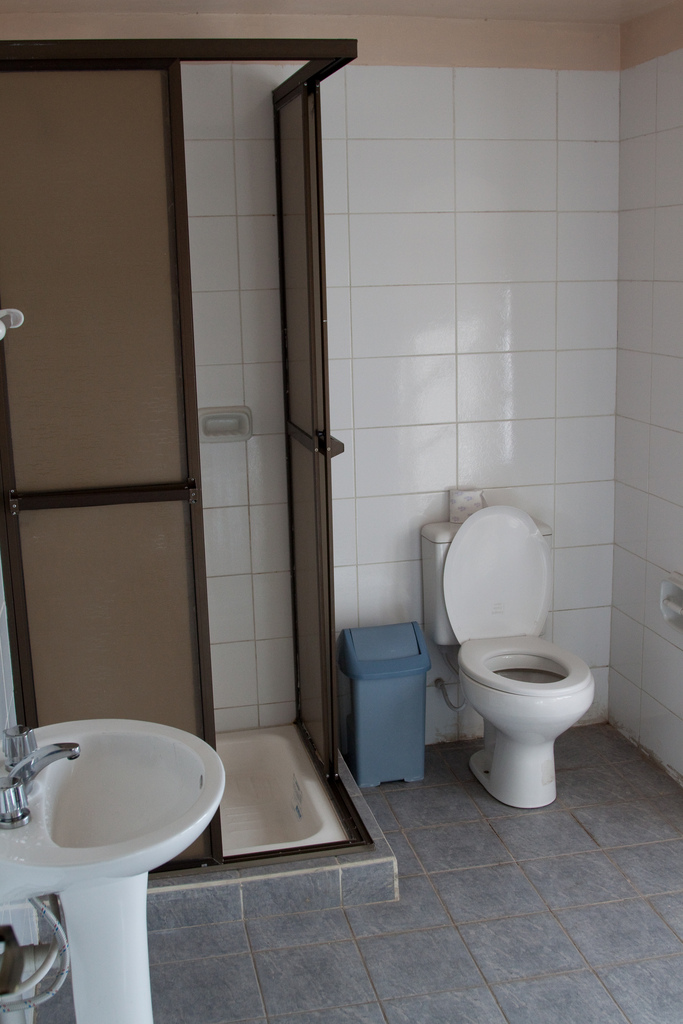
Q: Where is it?
A: This is at the bathroom.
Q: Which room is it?
A: It is a bathroom.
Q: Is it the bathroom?
A: Yes, it is the bathroom.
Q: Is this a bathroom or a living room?
A: It is a bathroom.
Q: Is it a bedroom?
A: No, it is a bathroom.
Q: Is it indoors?
A: Yes, it is indoors.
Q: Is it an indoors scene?
A: Yes, it is indoors.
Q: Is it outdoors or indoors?
A: It is indoors.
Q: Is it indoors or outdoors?
A: It is indoors.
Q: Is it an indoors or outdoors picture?
A: It is indoors.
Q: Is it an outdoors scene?
A: No, it is indoors.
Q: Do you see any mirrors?
A: No, there are no mirrors.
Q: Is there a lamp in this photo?
A: No, there are no lamps.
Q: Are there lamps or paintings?
A: No, there are no lamps or paintings.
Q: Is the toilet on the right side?
A: Yes, the toilet is on the right of the image.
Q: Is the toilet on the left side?
A: No, the toilet is on the right of the image.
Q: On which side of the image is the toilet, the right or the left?
A: The toilet is on the right of the image.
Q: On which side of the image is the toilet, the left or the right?
A: The toilet is on the right of the image.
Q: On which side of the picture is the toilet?
A: The toilet is on the right of the image.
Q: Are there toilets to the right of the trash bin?
A: Yes, there is a toilet to the right of the trash bin.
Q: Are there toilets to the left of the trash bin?
A: No, the toilet is to the right of the trash bin.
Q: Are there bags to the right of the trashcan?
A: No, there is a toilet to the right of the trashcan.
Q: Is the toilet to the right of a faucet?
A: No, the toilet is to the right of a trash can.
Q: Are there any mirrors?
A: No, there are no mirrors.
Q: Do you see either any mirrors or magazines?
A: No, there are no mirrors or magazines.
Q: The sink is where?
A: The sink is in the bathroom.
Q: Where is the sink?
A: The sink is in the bathroom.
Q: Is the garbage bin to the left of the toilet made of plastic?
A: Yes, the trash can is made of plastic.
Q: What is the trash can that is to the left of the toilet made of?
A: The garbage bin is made of plastic.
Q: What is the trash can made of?
A: The garbage bin is made of plastic.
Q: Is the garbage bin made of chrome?
A: No, the garbage bin is made of plastic.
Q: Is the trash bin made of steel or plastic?
A: The trash bin is made of plastic.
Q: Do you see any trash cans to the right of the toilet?
A: No, the trash can is to the left of the toilet.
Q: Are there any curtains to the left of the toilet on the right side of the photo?
A: No, there is a trash can to the left of the toilet.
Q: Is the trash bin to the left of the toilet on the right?
A: Yes, the trash bin is to the left of the toilet.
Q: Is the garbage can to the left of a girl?
A: No, the garbage can is to the left of the toilet.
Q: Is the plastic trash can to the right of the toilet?
A: No, the garbage bin is to the left of the toilet.